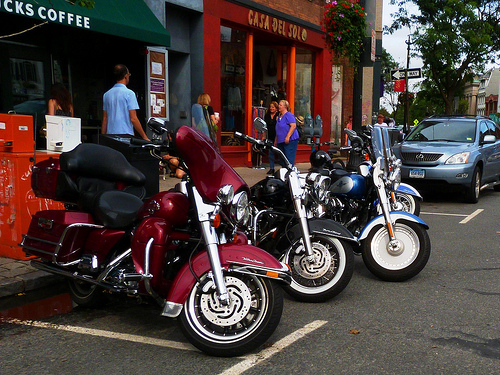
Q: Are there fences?
A: No, there are no fences.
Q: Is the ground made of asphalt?
A: Yes, the ground is made of asphalt.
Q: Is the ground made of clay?
A: No, the ground is made of asphalt.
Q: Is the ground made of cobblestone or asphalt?
A: The ground is made of asphalt.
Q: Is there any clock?
A: No, there are no clocks.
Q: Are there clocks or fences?
A: No, there are no clocks or fences.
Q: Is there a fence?
A: No, there are no fences.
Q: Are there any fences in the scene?
A: No, there are no fences.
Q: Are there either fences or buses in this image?
A: No, there are no fences or buses.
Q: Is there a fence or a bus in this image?
A: No, there are no fences or buses.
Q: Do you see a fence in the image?
A: No, there are no fences.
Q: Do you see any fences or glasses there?
A: No, there are no fences or glasses.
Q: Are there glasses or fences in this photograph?
A: No, there are no fences or glasses.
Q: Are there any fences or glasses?
A: No, there are no fences or glasses.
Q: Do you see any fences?
A: No, there are no fences.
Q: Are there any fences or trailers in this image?
A: No, there are no fences or trailers.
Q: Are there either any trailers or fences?
A: No, there are no fences or trailers.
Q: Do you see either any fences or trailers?
A: No, there are no fences or trailers.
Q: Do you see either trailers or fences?
A: No, there are no fences or trailers.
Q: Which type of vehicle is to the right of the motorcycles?
A: The vehicle is a car.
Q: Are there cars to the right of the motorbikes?
A: Yes, there is a car to the right of the motorbikes.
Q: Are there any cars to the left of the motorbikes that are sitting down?
A: No, the car is to the right of the motorbikes.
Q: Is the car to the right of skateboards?
A: No, the car is to the right of the motorcycles.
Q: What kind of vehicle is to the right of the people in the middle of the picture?
A: The vehicle is a car.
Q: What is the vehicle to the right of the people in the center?
A: The vehicle is a car.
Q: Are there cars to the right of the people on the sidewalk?
A: Yes, there is a car to the right of the people.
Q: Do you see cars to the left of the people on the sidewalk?
A: No, the car is to the right of the people.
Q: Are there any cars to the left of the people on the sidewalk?
A: No, the car is to the right of the people.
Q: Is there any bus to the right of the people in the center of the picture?
A: No, there is a car to the right of the people.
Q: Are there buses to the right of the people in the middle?
A: No, there is a car to the right of the people.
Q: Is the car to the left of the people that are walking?
A: No, the car is to the right of the people.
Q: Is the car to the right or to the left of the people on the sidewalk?
A: The car is to the right of the people.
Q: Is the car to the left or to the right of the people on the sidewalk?
A: The car is to the right of the people.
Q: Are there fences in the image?
A: No, there are no fences.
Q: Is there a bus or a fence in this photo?
A: No, there are no fences or buses.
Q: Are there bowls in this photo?
A: No, there are no bowls.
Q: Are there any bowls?
A: No, there are no bowls.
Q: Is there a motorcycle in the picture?
A: Yes, there are motorcycles.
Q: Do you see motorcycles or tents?
A: Yes, there are motorcycles.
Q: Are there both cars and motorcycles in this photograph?
A: Yes, there are both motorcycles and a car.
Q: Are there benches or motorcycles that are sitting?
A: Yes, the motorcycles are sitting.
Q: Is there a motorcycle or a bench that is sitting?
A: Yes, the motorcycles are sitting.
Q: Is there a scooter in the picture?
A: No, there are no scooters.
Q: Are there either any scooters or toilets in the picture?
A: No, there are no scooters or toilets.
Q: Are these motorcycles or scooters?
A: These are motorcycles.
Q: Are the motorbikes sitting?
A: Yes, the motorbikes are sitting.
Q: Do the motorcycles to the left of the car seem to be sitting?
A: Yes, the motorcycles are sitting.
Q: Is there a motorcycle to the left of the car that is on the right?
A: Yes, there are motorcycles to the left of the car.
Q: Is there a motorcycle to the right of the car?
A: No, the motorcycles are to the left of the car.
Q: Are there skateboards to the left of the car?
A: No, there are motorcycles to the left of the car.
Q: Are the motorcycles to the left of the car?
A: Yes, the motorcycles are to the left of the car.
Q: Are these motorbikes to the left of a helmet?
A: No, the motorbikes are to the left of the car.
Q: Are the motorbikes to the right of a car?
A: No, the motorbikes are to the left of a car.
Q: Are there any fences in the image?
A: No, there are no fences.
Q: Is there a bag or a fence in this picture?
A: No, there are no fences or bags.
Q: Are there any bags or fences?
A: No, there are no fences or bags.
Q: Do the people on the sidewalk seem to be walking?
A: Yes, the people are walking.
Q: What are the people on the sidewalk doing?
A: The people are walking.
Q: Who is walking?
A: The people are walking.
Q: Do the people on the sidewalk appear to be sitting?
A: No, the people are walking.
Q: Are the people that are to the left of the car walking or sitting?
A: The people are walking.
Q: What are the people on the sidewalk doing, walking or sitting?
A: The people are walking.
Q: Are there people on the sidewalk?
A: Yes, there are people on the sidewalk.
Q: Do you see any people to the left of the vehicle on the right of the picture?
A: Yes, there are people to the left of the car.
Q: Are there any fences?
A: No, there are no fences.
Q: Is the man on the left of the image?
A: Yes, the man is on the left of the image.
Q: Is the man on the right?
A: No, the man is on the left of the image.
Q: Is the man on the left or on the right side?
A: The man is on the left of the image.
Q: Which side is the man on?
A: The man is on the left of the image.